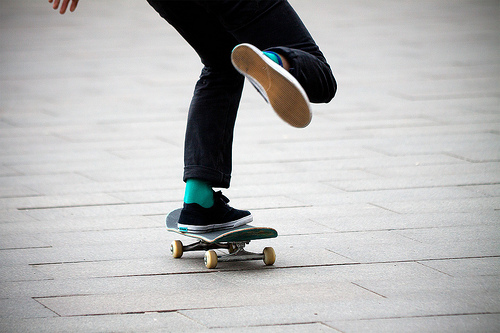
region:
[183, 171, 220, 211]
skater with green socks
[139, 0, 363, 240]
skater with black pants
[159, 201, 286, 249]
black skateboard with tan edge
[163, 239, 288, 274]
tan wheels of skateboard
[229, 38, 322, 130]
white edge of black shoe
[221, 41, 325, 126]
tan dirty sole of shoe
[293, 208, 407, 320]
grey squared concrete ground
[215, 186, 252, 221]
black shoe lace of shoe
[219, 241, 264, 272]
metal axle of skateboard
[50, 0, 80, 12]
fingers of skater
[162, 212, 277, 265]
this is a skateboard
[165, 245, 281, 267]
these are some wheels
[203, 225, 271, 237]
the skateboard is wooden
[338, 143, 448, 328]
this is the ground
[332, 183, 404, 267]
the ground is made of stone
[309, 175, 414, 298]
the ground is grey in color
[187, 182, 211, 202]
this is a sock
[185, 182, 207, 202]
the sock is green in color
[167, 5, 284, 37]
this is a pair of trousers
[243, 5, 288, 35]
the trouser is black in color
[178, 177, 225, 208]
green sock on skater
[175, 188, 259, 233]
black shoes on skater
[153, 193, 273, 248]
black skateboard with white trim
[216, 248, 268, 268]
metal axle on skateboard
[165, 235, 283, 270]
white wheels of skateboard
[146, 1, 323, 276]
black pants of skater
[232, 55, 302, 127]
dirty sole of shoe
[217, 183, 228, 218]
black lace of shoe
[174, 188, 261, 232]
black shoe with white trim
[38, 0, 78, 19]
finger of skater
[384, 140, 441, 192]
part of a surface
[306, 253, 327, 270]
part of a line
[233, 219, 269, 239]
edge of a board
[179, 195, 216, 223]
part of a shoe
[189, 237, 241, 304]
part of a wheel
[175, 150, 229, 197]
edge of a trouser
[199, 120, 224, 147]
part of a trouser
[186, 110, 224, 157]
part of a trouser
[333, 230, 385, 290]
part of a floor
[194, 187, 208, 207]
part of a sock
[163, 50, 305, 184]
these are two legs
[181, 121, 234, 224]
this is the left leg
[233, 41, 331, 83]
this is the right leg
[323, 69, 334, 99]
the knee is bent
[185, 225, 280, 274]
this is a skate board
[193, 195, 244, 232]
the leg is on the board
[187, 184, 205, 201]
the socks is blue in color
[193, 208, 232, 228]
the shoe is black in color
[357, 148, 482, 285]
this is the floor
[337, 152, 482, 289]
the floor is clean